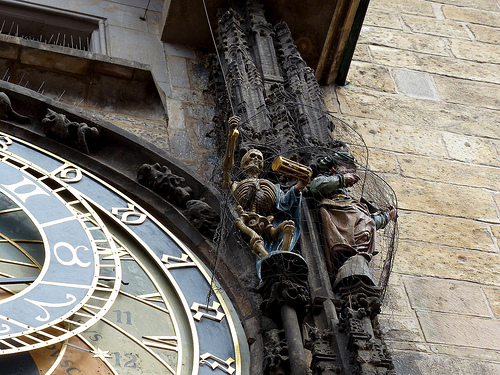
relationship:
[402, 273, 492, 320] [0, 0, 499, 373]
brick on wall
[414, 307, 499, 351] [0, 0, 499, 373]
brick on wall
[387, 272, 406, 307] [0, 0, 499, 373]
brick on wall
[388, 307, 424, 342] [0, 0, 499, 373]
brick on wall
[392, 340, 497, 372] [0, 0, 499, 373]
brick on wall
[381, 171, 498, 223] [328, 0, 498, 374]
brick on stone wall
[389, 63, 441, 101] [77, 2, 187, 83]
brick on wall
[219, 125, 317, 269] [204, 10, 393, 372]
skeleton on pillar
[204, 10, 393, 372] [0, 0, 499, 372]
pillar on building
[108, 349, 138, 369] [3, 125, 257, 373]
12 on clock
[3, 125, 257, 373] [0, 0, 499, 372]
clock on building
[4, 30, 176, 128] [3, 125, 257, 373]
ledge above clock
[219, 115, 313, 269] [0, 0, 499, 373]
skeleton on wall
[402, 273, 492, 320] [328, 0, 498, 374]
brick on stone wall